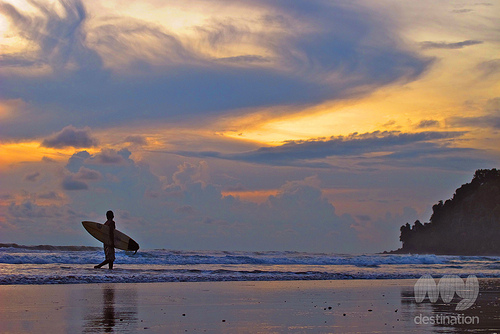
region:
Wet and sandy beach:
[3, 286, 410, 328]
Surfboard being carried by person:
[82, 217, 142, 249]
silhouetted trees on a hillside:
[393, 215, 424, 247]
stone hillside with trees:
[400, 182, 480, 250]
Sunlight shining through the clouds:
[220, 107, 442, 144]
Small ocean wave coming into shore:
[9, 252, 445, 265]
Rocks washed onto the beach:
[179, 308, 229, 323]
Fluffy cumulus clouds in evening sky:
[162, 158, 353, 251]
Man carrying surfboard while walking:
[81, 207, 141, 270]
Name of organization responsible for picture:
[398, 264, 483, 326]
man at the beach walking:
[86, 190, 146, 280]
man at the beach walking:
[66, 190, 173, 305]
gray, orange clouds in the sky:
[42, 87, 385, 250]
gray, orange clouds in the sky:
[46, 113, 255, 205]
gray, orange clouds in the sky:
[253, 103, 373, 233]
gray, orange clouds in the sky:
[108, 48, 348, 187]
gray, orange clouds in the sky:
[152, 107, 347, 297]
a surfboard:
[77, 216, 103, 242]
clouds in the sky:
[75, 27, 253, 135]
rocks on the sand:
[315, 284, 370, 323]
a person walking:
[93, 202, 130, 269]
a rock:
[426, 178, 498, 257]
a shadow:
[97, 281, 127, 321]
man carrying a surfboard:
[77, 205, 137, 251]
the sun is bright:
[230, 118, 314, 154]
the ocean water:
[197, 245, 303, 279]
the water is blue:
[196, 243, 307, 276]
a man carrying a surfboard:
[66, 200, 147, 280]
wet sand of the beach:
[147, 288, 338, 321]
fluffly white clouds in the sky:
[156, 154, 361, 232]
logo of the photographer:
[372, 256, 499, 327]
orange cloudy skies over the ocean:
[18, 15, 437, 159]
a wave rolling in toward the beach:
[150, 249, 453, 268]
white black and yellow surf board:
[78, 220, 142, 250]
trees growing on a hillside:
[381, 170, 497, 252]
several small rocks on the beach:
[313, 298, 413, 328]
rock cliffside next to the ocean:
[433, 203, 498, 250]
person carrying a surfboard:
[78, 203, 148, 278]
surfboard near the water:
[77, 215, 144, 257]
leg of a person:
[88, 248, 115, 270]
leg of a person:
[105, 255, 117, 270]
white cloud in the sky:
[220, 113, 468, 170]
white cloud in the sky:
[32, 120, 108, 150]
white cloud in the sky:
[55, 174, 89, 194]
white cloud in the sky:
[412, 115, 446, 133]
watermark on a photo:
[402, 270, 490, 330]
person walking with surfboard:
[77, 205, 144, 272]